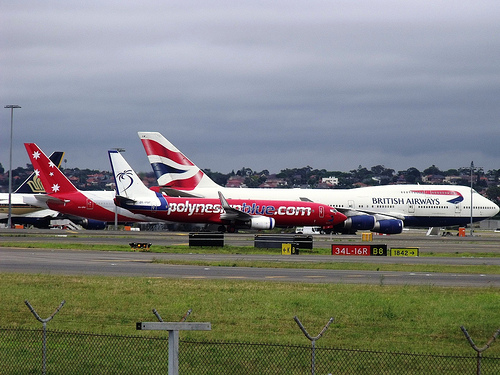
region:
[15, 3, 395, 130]
gray clouds in the sky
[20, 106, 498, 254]
planes at the airport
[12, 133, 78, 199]
the tail of the plane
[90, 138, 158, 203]
the tail of the plane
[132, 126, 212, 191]
the tail of the plane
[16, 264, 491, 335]
grass by the runway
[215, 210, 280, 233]
the engine of the plane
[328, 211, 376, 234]
the engine of the plane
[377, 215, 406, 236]
the engine of the plane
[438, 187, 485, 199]
the cockpit of the plane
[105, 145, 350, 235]
red, white and blue jet airliner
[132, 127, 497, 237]
red, white and blue jet airliner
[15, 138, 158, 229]
red, white and blue jet airliner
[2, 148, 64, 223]
black, white and yellow jet airliner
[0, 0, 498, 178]
gray cloudy overcast sky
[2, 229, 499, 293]
asphalt paved plane run way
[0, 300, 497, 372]
tall chain link fence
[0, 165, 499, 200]
many homes and trees on a hill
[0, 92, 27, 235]
tall light on a grey metal pole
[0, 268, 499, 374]
stretch of green grass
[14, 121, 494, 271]
planes on a runway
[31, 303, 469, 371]
metal fence by an airport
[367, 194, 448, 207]
name of the airplane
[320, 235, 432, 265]
signs on a fence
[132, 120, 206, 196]
tail of a plane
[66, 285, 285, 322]
green grass at an airport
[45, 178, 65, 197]
star on a plane's tail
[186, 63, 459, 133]
cloudy sky in the distance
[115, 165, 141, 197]
palm tree on a plane's tail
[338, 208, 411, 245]
engines on a plane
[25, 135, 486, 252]
planes are on the runway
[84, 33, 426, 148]
dark gray clouds filling the sky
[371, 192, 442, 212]
British Airways name on side of plane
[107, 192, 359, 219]
red and blue plane is parked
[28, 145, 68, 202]
plane has white stars on the tail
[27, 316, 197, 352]
metal link fence around the runway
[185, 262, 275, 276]
asphalt paves the runway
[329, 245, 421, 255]
airplane traffic markers for pilots to follow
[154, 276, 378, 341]
grassy field beside the runway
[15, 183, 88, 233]
plane is parked at the gate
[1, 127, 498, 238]
Airplanes next to each other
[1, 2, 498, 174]
The sky is very cloudy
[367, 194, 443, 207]
"BRITISH AIRWAYS" on side of the plane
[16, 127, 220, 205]
Four tails of the planes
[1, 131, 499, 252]
Planes are on the runway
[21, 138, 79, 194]
White stars on the tail of a plane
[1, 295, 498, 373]
A fence in front of the runway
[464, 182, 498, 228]
The nose of a plane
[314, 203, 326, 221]
A door on an airplane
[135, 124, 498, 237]
The airplane is mostly white